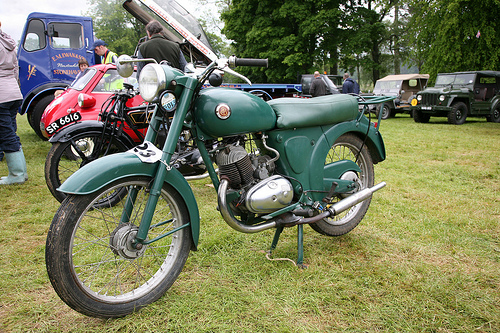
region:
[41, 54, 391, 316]
a green parked motorcycle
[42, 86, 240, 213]
a black parked motorcycle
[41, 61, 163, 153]
a small red vehicle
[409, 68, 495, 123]
a parked green Jeep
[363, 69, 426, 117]
a parked brown Jeep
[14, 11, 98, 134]
a blue truck cab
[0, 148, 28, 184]
light green mud boots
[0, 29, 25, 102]
a light pink winter coat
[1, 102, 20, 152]
a pair of blue jeans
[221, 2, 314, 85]
large green tree in distance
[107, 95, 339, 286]
green bike on grass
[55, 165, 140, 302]
black wheels on bike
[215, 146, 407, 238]
chrome pipe on bike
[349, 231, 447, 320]
green and brown grass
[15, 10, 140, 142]
red car behind bikes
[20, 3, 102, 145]
blue truck behind car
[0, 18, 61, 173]
girl stands near truck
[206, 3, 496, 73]
green trees in background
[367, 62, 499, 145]
black truck is parked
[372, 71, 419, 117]
brown cover on truck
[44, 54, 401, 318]
Motorcycle parked on the grass.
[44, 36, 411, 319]
Green motorcycle old school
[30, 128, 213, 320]
motercycle wheel black moter cycle in background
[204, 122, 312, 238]
Small engine with chrome and on a green frame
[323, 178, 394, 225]
small exhaust pipe pointed behind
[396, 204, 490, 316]
Grass with a dead patch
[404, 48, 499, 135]
Jeep car with door missing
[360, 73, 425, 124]
Old jeep car with soft top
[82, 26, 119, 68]
Man looking down moving forward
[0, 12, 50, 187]
Girl with boots on in pink jacket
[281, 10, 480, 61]
Forest with pine trees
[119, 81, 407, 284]
green frame on bike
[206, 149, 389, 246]
chrome pipe on bike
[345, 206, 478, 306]
green and brown grass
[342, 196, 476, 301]
grass is short and thick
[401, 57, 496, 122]
black jeep is parked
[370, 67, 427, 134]
brown cover on jeep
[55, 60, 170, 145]
small and red car